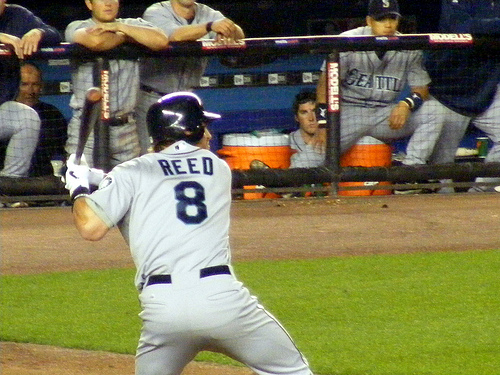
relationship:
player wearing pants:
[65, 91, 314, 373] [133, 264, 315, 374]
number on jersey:
[174, 180, 209, 225] [86, 140, 232, 291]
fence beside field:
[1, 33, 499, 208] [0, 192, 499, 374]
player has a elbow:
[65, 91, 314, 373] [77, 223, 101, 241]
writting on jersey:
[159, 156, 213, 176] [86, 140, 232, 291]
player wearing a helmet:
[65, 91, 314, 373] [145, 91, 221, 144]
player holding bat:
[65, 91, 314, 373] [74, 89, 101, 164]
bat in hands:
[74, 89, 101, 164] [64, 152, 92, 187]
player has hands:
[65, 91, 314, 373] [64, 152, 92, 187]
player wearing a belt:
[65, 91, 314, 373] [144, 264, 232, 287]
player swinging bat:
[65, 91, 314, 373] [74, 89, 101, 164]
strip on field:
[2, 190, 498, 270] [0, 192, 499, 374]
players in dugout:
[0, 0, 499, 207] [0, 0, 499, 207]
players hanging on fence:
[0, 0, 499, 207] [1, 33, 499, 208]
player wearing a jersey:
[65, 91, 314, 373] [86, 140, 232, 291]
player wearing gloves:
[65, 91, 314, 373] [64, 152, 107, 200]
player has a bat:
[65, 91, 314, 373] [74, 89, 101, 164]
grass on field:
[0, 247, 499, 374] [0, 192, 499, 374]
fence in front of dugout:
[1, 33, 499, 208] [0, 0, 499, 207]